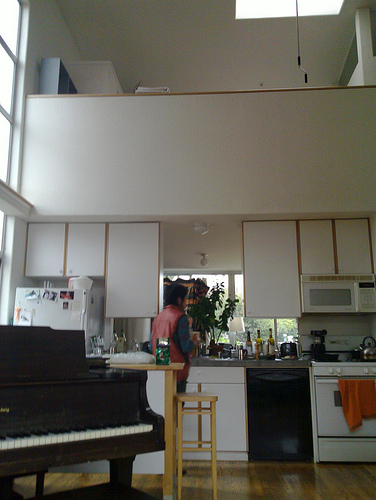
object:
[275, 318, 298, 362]
window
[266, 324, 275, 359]
bottle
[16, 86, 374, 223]
wall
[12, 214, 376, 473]
kitchen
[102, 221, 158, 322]
door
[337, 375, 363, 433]
towel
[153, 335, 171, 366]
bottle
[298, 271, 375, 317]
microwave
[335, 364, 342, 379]
knob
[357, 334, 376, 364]
kettle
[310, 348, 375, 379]
stove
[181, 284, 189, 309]
face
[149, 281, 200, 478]
person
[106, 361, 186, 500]
table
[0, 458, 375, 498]
floor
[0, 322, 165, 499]
piano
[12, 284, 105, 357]
fridge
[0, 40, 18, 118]
window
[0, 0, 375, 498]
room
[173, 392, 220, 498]
stool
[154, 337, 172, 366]
package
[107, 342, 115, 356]
glass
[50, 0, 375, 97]
ceiling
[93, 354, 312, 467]
counter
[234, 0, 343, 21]
light